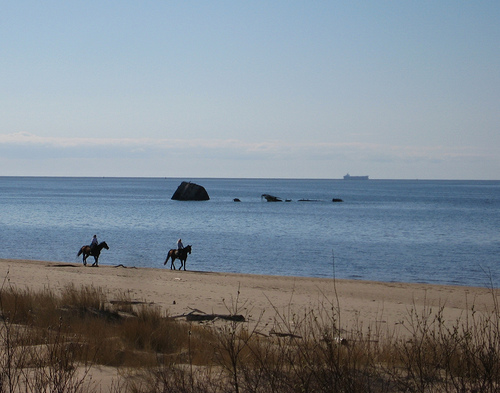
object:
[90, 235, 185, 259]
two people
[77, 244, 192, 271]
two horses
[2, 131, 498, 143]
line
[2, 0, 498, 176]
sky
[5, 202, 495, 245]
shallow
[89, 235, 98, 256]
horsemen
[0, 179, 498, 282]
ocean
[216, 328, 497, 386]
plants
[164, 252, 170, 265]
tail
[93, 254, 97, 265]
legs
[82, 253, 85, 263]
legs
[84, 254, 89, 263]
legs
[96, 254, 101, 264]
legs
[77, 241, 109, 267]
horses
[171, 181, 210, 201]
rock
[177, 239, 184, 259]
person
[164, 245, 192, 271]
horse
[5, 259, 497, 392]
beach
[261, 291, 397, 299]
sand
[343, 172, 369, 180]
ship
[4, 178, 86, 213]
water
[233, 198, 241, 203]
items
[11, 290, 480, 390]
grass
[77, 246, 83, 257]
tail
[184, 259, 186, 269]
legs